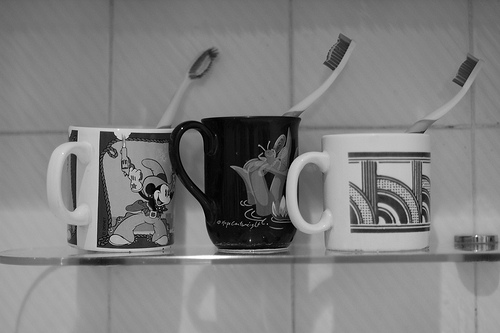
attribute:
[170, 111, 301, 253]
cup — black, for coffee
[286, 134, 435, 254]
mug — patterned, white, ceramic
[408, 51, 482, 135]
toothbrush — white, bristled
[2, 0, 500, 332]
wall — tiled, white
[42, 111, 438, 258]
cups — together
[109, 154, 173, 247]
mickey mouse — present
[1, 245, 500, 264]
shelf — glass, silver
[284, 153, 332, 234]
handle — white